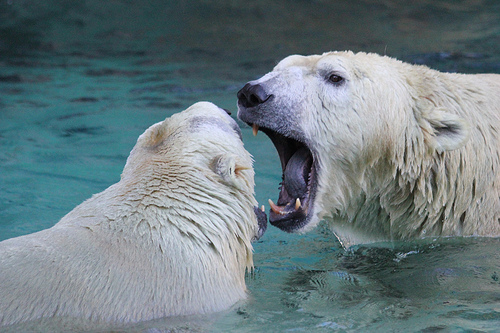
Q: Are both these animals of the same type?
A: Yes, all the animals are bears.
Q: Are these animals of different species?
A: No, all the animals are bears.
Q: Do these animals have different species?
A: No, all the animals are bears.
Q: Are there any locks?
A: No, there are no locks.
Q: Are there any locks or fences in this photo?
A: No, there are no locks or fences.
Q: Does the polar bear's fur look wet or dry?
A: The fur is wet.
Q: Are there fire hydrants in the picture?
A: No, there are no fire hydrants.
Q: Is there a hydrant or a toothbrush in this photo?
A: No, there are no fire hydrants or toothbrushes.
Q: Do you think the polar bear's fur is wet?
A: Yes, the fur is wet.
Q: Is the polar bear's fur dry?
A: No, the fur is wet.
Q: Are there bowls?
A: No, there are no bowls.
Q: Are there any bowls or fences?
A: No, there are no bowls or fences.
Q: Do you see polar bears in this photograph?
A: Yes, there is a polar bear.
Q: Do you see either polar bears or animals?
A: Yes, there is a polar bear.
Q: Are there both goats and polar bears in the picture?
A: No, there is a polar bear but no goats.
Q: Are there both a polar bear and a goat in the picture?
A: No, there is a polar bear but no goats.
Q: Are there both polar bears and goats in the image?
A: No, there is a polar bear but no goats.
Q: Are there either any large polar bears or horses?
A: Yes, there is a large polar bear.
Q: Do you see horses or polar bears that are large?
A: Yes, the polar bear is large.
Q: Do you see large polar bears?
A: Yes, there is a large polar bear.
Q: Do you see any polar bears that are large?
A: Yes, there is a large polar bear.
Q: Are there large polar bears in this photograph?
A: Yes, there is a large polar bear.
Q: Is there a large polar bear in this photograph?
A: Yes, there is a large polar bear.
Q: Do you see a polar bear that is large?
A: Yes, there is a polar bear that is large.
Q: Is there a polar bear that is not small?
A: Yes, there is a large polar bear.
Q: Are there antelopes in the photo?
A: No, there are no antelopes.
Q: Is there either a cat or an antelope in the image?
A: No, there are no antelopes or cats.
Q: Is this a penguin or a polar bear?
A: This is a polar bear.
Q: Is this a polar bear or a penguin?
A: This is a polar bear.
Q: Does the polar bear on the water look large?
A: Yes, the polar bear is large.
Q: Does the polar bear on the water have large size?
A: Yes, the polar bear is large.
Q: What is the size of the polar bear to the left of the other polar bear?
A: The polar bear is large.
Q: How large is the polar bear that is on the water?
A: The polar bear is large.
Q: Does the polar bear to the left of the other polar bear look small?
A: No, the polar bear is large.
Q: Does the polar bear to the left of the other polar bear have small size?
A: No, the polar bear is large.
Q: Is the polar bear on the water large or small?
A: The polar bear is large.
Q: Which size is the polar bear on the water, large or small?
A: The polar bear is large.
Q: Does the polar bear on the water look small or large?
A: The polar bear is large.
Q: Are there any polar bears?
A: Yes, there is a polar bear.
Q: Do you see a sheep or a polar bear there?
A: Yes, there is a polar bear.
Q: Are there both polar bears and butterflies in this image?
A: No, there is a polar bear but no butterflies.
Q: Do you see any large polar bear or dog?
A: Yes, there is a large polar bear.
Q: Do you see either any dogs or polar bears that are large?
A: Yes, the polar bear is large.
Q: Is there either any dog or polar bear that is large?
A: Yes, the polar bear is large.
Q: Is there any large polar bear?
A: Yes, there is a large polar bear.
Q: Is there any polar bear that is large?
A: Yes, there is a polar bear that is large.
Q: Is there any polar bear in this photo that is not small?
A: Yes, there is a large polar bear.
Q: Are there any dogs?
A: No, there are no dogs.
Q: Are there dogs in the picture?
A: No, there are no dogs.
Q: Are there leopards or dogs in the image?
A: No, there are no dogs or leopards.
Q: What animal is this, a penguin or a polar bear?
A: This is a polar bear.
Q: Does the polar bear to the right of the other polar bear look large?
A: Yes, the polar bear is large.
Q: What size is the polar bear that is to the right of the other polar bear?
A: The polar bear is large.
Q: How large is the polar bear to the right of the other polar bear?
A: The polar bear is large.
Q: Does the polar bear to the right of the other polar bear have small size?
A: No, the polar bear is large.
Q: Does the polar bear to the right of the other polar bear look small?
A: No, the polar bear is large.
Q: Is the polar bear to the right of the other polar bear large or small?
A: The polar bear is large.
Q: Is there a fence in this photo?
A: No, there are no fences.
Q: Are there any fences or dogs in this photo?
A: No, there are no fences or dogs.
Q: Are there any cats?
A: No, there are no cats.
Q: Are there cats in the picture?
A: No, there are no cats.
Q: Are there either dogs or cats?
A: No, there are no cats or dogs.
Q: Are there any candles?
A: No, there are no candles.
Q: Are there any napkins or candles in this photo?
A: No, there are no candles or napkins.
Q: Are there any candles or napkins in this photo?
A: No, there are no candles or napkins.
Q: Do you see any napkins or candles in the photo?
A: No, there are no candles or napkins.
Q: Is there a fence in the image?
A: No, there are no fences.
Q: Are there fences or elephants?
A: No, there are no fences or elephants.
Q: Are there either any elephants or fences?
A: No, there are no fences or elephants.